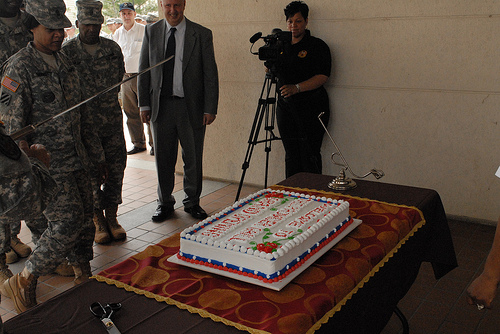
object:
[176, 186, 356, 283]
cake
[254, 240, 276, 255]
flower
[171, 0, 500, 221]
wall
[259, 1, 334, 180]
woman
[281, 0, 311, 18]
hair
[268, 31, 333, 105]
shirt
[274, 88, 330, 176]
pants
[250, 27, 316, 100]
camera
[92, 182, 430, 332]
cloth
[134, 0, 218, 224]
man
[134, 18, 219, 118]
coat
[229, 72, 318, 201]
tripod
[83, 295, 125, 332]
scissors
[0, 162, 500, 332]
table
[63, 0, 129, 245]
soldier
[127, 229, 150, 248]
tile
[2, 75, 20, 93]
flag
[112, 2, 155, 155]
man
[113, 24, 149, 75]
shirt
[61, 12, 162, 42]
people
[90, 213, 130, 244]
boots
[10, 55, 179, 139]
blade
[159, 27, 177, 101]
tie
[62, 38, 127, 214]
uniform